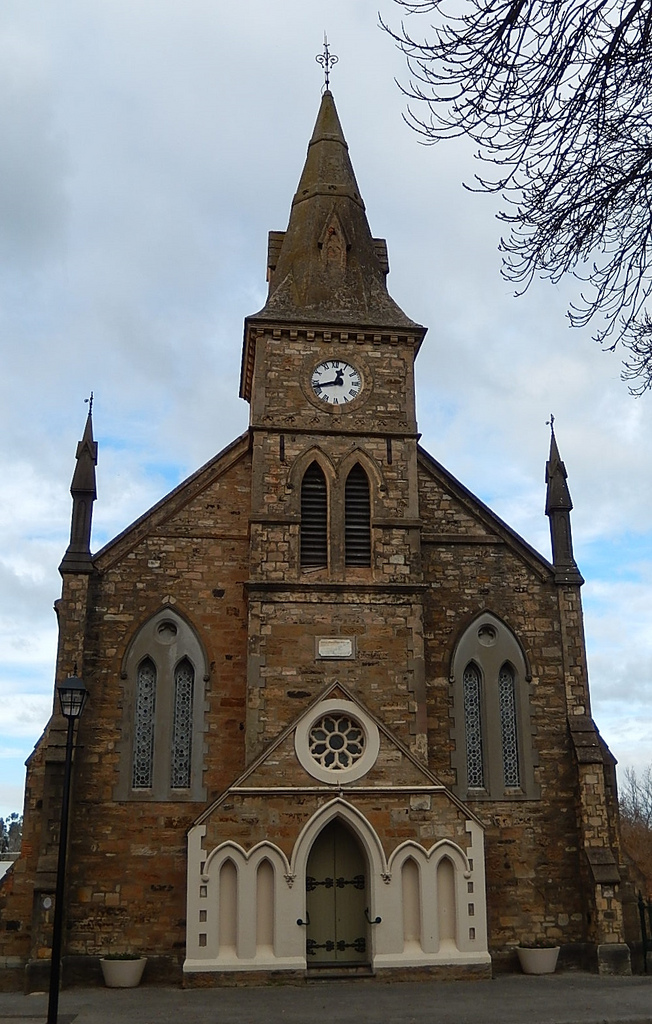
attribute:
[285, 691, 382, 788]
design — circle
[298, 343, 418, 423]
clock — white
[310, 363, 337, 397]
numerals — black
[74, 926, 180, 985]
planter — tan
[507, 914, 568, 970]
planter — tan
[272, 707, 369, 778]
window — circular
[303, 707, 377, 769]
decoration — gothic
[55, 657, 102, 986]
lamp post — old fashion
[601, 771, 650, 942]
leaves — orange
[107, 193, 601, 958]
church — large brown stone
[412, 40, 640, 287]
tree — leafless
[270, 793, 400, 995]
door — closed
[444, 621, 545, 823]
window — stained glass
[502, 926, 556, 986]
plants — potted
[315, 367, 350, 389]
hands — black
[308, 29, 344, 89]
top — metal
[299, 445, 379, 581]
shutters — wooden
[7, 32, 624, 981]
church — big, brick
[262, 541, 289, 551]
brick — brown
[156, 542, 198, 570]
brick — brown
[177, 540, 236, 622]
brick — brown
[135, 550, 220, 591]
brick — brown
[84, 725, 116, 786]
brick — brown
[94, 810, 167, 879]
brick — brown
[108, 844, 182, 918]
brick — brown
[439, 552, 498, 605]
brick — brown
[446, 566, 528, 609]
brick — brown